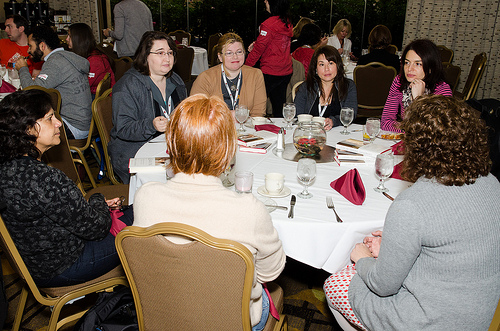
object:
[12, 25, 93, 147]
man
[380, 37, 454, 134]
woman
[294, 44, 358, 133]
woman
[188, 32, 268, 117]
woman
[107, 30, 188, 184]
woman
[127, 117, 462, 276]
table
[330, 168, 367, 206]
napkin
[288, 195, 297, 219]
knife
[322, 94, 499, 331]
woman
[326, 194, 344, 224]
fork